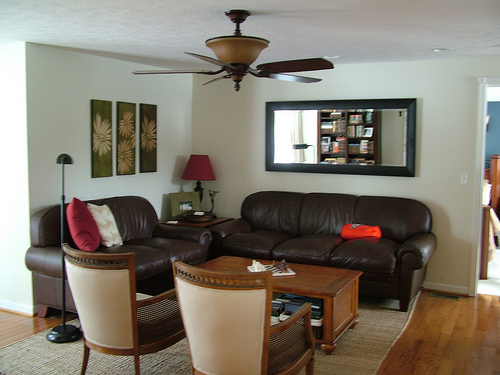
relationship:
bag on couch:
[338, 221, 384, 242] [222, 186, 438, 311]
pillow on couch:
[63, 195, 102, 253] [26, 195, 211, 319]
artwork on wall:
[85, 98, 167, 179] [29, 48, 199, 234]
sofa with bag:
[220, 186, 445, 282] [335, 208, 381, 248]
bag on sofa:
[338, 221, 384, 242] [210, 190, 437, 311]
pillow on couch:
[82, 197, 127, 248] [25, 196, 213, 318]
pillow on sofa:
[58, 194, 104, 252] [210, 190, 437, 311]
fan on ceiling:
[119, 45, 374, 115] [359, 4, 479, 82]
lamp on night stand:
[162, 152, 254, 234] [165, 203, 235, 241]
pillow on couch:
[85, 202, 124, 249] [25, 196, 213, 318]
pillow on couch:
[58, 194, 104, 252] [25, 196, 213, 318]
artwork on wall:
[87, 98, 114, 180] [29, 64, 85, 128]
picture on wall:
[113, 100, 138, 176] [29, 64, 85, 128]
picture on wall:
[138, 101, 158, 174] [29, 64, 85, 128]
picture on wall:
[138, 101, 155, 172] [25, 42, 194, 218]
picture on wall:
[115, 100, 136, 175] [25, 42, 194, 218]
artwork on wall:
[87, 98, 114, 180] [25, 42, 194, 218]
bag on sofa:
[338, 221, 381, 238] [209, 185, 436, 312]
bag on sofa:
[338, 221, 384, 242] [209, 185, 436, 312]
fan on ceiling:
[128, 9, 334, 92] [1, 2, 496, 77]